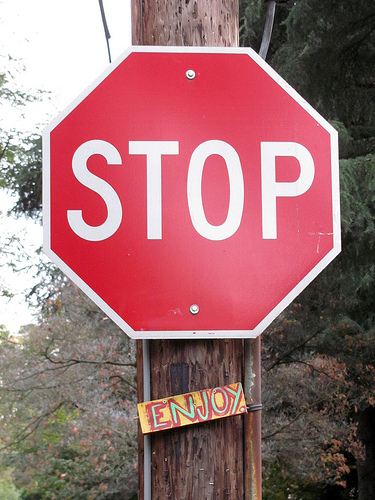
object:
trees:
[0, 0, 375, 500]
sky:
[0, 0, 131, 341]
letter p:
[257, 137, 316, 244]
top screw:
[182, 66, 198, 83]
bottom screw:
[188, 304, 200, 315]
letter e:
[148, 400, 172, 428]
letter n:
[167, 391, 199, 423]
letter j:
[194, 386, 212, 420]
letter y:
[223, 380, 249, 414]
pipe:
[245, 331, 261, 497]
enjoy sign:
[136, 381, 248, 434]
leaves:
[344, 7, 354, 21]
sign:
[134, 380, 250, 435]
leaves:
[327, 435, 337, 447]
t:
[125, 137, 179, 241]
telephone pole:
[129, 0, 242, 499]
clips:
[246, 402, 264, 413]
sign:
[41, 44, 342, 337]